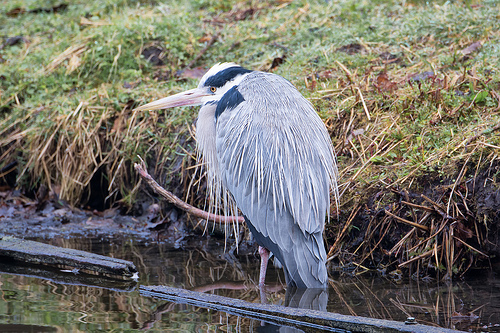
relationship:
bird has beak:
[167, 87, 363, 311] [143, 84, 204, 110]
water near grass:
[65, 210, 170, 263] [57, 30, 144, 148]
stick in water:
[72, 248, 238, 330] [65, 210, 170, 263]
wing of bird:
[216, 130, 324, 220] [167, 87, 363, 311]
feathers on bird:
[181, 150, 245, 231] [167, 87, 363, 311]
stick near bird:
[72, 248, 238, 330] [167, 87, 363, 311]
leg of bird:
[140, 167, 243, 253] [167, 87, 363, 311]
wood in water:
[25, 224, 89, 272] [65, 210, 170, 263]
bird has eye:
[167, 87, 363, 311] [205, 83, 235, 100]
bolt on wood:
[382, 305, 420, 332] [25, 224, 89, 272]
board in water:
[169, 283, 393, 332] [65, 210, 170, 263]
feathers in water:
[181, 150, 245, 231] [65, 210, 170, 263]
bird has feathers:
[167, 87, 363, 311] [181, 150, 245, 231]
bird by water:
[167, 87, 363, 311] [65, 210, 170, 263]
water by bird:
[65, 210, 170, 263] [167, 87, 363, 311]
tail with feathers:
[267, 232, 342, 292] [181, 150, 245, 231]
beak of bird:
[143, 84, 204, 110] [167, 87, 363, 311]